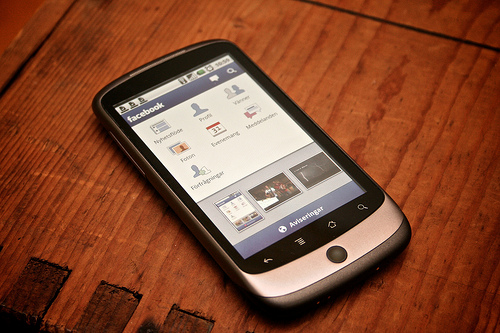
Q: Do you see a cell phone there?
A: Yes, there is a cell phone.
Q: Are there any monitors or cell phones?
A: Yes, there is a cell phone.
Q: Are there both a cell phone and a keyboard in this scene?
A: No, there is a cell phone but no keyboards.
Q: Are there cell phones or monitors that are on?
A: Yes, the cell phone is on.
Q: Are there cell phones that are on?
A: Yes, there is a cell phone that is on.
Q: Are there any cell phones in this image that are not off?
A: Yes, there is a cell phone that is on.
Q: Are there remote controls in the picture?
A: No, there are no remote controls.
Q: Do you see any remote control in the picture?
A: No, there are no remote controls.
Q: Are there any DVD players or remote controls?
A: No, there are no remote controls or DVD players.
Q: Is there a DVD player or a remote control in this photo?
A: No, there are no remote controls or DVD players.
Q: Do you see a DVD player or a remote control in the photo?
A: No, there are no remote controls or DVD players.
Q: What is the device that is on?
A: The device is a cell phone.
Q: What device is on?
A: The device is a cell phone.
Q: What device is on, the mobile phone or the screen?
A: The mobile phone is on.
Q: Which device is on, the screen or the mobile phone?
A: The mobile phone is on.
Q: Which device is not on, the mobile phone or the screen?
A: The screen is not on.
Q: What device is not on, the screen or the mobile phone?
A: The screen is not on.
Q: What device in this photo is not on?
A: The device is a screen.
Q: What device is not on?
A: The device is a screen.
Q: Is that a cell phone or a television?
A: That is a cell phone.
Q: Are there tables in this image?
A: Yes, there is a table.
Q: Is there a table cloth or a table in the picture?
A: Yes, there is a table.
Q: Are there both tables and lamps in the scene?
A: No, there is a table but no lamps.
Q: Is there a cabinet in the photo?
A: No, there are no cabinets.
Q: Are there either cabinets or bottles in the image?
A: No, there are no cabinets or bottles.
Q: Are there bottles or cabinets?
A: No, there are no cabinets or bottles.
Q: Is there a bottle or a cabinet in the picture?
A: No, there are no cabinets or bottles.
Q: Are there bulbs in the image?
A: No, there are no bulbs.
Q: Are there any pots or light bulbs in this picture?
A: No, there are no light bulbs or pots.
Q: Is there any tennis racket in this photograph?
A: No, there are no rackets.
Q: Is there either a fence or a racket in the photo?
A: No, there are no rackets or fences.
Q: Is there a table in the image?
A: Yes, there is a table.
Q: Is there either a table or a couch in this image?
A: Yes, there is a table.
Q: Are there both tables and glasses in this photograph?
A: No, there is a table but no glasses.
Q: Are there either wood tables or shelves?
A: Yes, there is a wood table.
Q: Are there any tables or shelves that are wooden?
A: Yes, the table is wooden.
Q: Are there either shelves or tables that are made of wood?
A: Yes, the table is made of wood.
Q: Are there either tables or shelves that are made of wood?
A: Yes, the table is made of wood.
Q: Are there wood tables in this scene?
A: Yes, there is a wood table.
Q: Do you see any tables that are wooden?
A: Yes, there is a wood table.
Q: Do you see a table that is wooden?
A: Yes, there is a table that is wooden.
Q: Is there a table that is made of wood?
A: Yes, there is a table that is made of wood.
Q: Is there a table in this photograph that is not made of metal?
A: Yes, there is a table that is made of wood.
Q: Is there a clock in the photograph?
A: No, there are no clocks.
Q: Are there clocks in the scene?
A: No, there are no clocks.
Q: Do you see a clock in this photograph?
A: No, there are no clocks.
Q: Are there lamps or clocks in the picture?
A: No, there are no clocks or lamps.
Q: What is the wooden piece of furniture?
A: The piece of furniture is a table.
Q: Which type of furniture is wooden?
A: The furniture is a table.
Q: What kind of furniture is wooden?
A: The furniture is a table.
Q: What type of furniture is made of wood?
A: The furniture is a table.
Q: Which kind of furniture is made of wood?
A: The furniture is a table.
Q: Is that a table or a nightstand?
A: That is a table.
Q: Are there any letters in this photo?
A: Yes, there are letters.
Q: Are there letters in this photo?
A: Yes, there are letters.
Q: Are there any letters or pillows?
A: Yes, there are letters.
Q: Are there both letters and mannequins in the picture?
A: No, there are letters but no mannequins.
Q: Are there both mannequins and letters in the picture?
A: No, there are letters but no mannequins.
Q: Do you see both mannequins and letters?
A: No, there are letters but no mannequins.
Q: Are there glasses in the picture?
A: No, there are no glasses.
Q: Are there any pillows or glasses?
A: No, there are no glasses or pillows.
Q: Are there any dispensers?
A: No, there are no dispensers.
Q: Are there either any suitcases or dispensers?
A: No, there are no dispensers or suitcases.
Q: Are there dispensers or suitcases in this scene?
A: No, there are no dispensers or suitcases.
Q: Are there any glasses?
A: No, there are no glasses.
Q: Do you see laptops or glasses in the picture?
A: No, there are no glasses or laptops.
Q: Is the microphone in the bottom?
A: Yes, the microphone is in the bottom of the image.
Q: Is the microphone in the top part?
A: No, the microphone is in the bottom of the image.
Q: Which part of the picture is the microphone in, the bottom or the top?
A: The microphone is in the bottom of the image.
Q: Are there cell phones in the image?
A: Yes, there is a cell phone.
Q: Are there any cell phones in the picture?
A: Yes, there is a cell phone.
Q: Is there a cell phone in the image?
A: Yes, there is a cell phone.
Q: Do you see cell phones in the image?
A: Yes, there is a cell phone.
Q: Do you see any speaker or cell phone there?
A: Yes, there is a cell phone.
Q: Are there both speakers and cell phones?
A: No, there is a cell phone but no speakers.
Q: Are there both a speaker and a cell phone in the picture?
A: No, there is a cell phone but no speakers.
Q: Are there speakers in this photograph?
A: No, there are no speakers.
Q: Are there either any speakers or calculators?
A: No, there are no speakers or calculators.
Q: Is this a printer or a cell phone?
A: This is a cell phone.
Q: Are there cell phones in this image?
A: Yes, there is a cell phone.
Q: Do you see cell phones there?
A: Yes, there is a cell phone.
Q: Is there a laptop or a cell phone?
A: Yes, there is a cell phone.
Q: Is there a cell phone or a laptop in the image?
A: Yes, there is a cell phone.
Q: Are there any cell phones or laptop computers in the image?
A: Yes, there is a cell phone.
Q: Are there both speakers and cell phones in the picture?
A: No, there is a cell phone but no speakers.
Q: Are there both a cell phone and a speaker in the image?
A: No, there is a cell phone but no speakers.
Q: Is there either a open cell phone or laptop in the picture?
A: Yes, there is an open cell phone.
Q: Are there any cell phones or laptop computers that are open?
A: Yes, the cell phone is open.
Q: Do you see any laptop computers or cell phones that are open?
A: Yes, the cell phone is open.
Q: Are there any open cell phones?
A: Yes, there is an open cell phone.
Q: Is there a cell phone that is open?
A: Yes, there is a cell phone that is open.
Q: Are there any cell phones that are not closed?
A: Yes, there is a open cell phone.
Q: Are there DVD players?
A: No, there are no DVD players.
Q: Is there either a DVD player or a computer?
A: No, there are no DVD players or computers.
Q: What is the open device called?
A: The device is a cell phone.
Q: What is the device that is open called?
A: The device is a cell phone.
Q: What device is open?
A: The device is a cell phone.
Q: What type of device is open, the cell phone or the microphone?
A: The cell phone is open.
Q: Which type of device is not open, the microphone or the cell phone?
A: The microphone is not open.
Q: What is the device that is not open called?
A: The device is a microphone.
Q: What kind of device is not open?
A: The device is a microphone.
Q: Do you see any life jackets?
A: No, there are no life jackets.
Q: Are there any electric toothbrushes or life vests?
A: No, there are no life vests or electric toothbrushes.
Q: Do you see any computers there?
A: No, there are no computers.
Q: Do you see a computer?
A: No, there are no computers.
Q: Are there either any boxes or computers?
A: No, there are no computers or boxes.